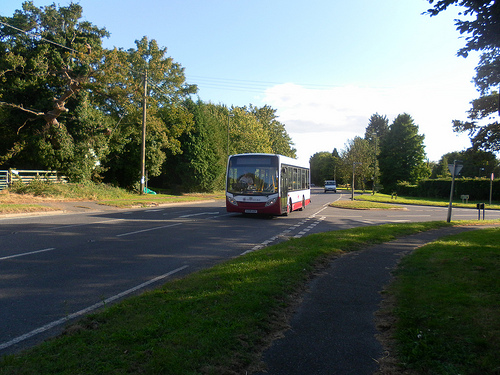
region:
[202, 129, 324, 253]
bus ia driving down the road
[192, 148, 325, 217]
the bus is white and red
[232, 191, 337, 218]
the bottom of the bus is red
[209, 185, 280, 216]
the headlights are on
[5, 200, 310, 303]
shadow of the trees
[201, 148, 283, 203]
the bus driver is driving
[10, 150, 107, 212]
a fence to the left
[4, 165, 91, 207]
the fence is grey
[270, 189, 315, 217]
the wheels are black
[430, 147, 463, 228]
a pole on the corner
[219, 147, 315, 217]
a red and white bus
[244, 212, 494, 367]
a gray cement sidewalk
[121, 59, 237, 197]
electrical wires and a wooden post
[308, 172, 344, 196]
a white van on the road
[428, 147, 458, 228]
a sign post near the road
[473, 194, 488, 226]
a mailbox near the road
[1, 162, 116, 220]
a railing in front of a driveway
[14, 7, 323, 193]
a row of trees near the road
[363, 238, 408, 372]
mowed grass next to the sidewalk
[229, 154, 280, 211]
a blank display on the front of the bus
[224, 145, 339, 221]
bus on the street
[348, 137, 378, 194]
tree on side of road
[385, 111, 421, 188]
tree on side of road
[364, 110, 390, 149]
tree on side of road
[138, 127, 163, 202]
tree on side of road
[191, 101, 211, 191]
tree on side of road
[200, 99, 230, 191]
tree on side of road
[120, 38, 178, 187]
tree on side of road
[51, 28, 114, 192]
tree on side of road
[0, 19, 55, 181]
tree on side of road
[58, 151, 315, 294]
a red and white bus on a road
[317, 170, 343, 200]
a vehicle on the road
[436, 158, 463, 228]
the back of a street sign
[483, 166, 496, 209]
a street sign on the right side of the road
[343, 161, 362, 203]
a street sign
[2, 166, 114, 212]
a gate in front of a driveway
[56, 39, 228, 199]
a wooden post and electrical wires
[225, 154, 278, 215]
a display that is not turned on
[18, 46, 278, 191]
a row of green trees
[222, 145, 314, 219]
A red and white bus.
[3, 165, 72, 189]
A fence on side of road.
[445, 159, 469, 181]
A triangle street sign.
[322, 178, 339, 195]
A white vehicle on road.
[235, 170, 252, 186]
A man driving bus.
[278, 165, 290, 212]
Doors on side of bus.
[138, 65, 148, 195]
A brown wooden street pole.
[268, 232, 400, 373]
A black concrete sidewalk.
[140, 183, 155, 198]
Green plastic on grass.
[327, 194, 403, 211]
Grassy median in road.